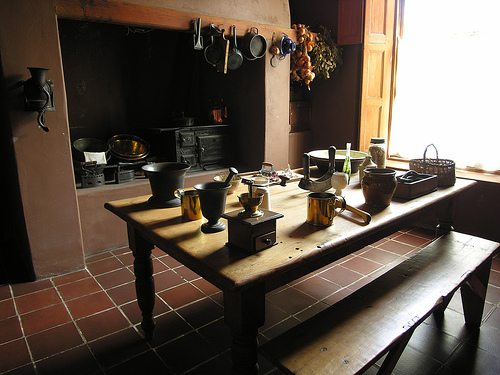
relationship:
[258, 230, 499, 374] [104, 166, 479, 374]
wooden bench of table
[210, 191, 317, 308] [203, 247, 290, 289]
top of table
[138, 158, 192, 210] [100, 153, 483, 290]
small/black bucket on table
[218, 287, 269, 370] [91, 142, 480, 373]
leg of table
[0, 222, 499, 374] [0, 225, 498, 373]
red tile on ground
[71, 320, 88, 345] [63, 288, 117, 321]
grout of tile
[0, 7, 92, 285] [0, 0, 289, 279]
brown wall on brown wall